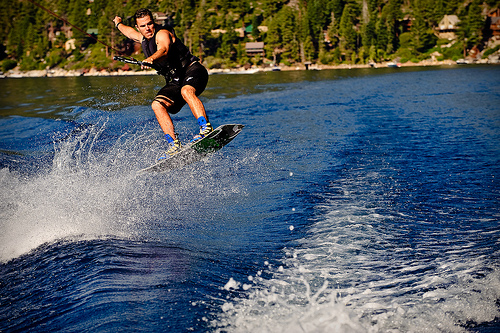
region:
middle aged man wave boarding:
[109, 12, 244, 175]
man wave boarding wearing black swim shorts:
[110, 11, 229, 163]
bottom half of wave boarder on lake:
[94, 94, 271, 253]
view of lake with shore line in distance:
[243, 3, 464, 154]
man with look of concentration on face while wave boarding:
[91, 7, 240, 168]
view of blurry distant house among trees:
[407, 7, 486, 49]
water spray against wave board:
[57, 126, 250, 253]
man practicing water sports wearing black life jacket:
[107, 11, 244, 172]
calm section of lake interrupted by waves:
[3, 86, 118, 145]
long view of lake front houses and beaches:
[214, 26, 380, 80]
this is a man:
[114, 3, 226, 128]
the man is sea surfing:
[98, 9, 225, 148]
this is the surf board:
[195, 118, 247, 167]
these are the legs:
[153, 87, 205, 127]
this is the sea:
[390, 93, 471, 166]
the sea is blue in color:
[393, 78, 485, 158]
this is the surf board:
[215, 120, 247, 146]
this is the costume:
[176, 42, 196, 74]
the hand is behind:
[112, 8, 131, 41]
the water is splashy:
[59, 123, 142, 185]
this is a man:
[110, 12, 222, 137]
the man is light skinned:
[153, 29, 170, 52]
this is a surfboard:
[165, 132, 232, 167]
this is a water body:
[303, 103, 466, 203]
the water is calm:
[309, 105, 454, 231]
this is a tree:
[336, 15, 361, 69]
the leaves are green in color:
[300, 34, 313, 57]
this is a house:
[243, 37, 268, 56]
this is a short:
[186, 67, 211, 88]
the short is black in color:
[190, 65, 205, 84]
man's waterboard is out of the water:
[72, 111, 288, 188]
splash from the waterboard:
[35, 120, 296, 263]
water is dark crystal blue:
[38, 227, 225, 320]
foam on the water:
[317, 161, 437, 330]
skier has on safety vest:
[132, 30, 221, 109]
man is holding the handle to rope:
[98, 49, 168, 88]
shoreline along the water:
[216, 59, 481, 74]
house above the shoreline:
[233, 31, 280, 60]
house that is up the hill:
[427, 12, 471, 50]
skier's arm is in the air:
[105, 8, 153, 50]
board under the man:
[101, 100, 251, 200]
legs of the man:
[140, 76, 215, 143]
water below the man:
[157, 187, 247, 272]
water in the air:
[45, 116, 116, 176]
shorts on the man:
[150, 55, 225, 105]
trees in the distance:
[260, 15, 385, 60]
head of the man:
[120, 5, 165, 41]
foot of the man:
[180, 111, 220, 146]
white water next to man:
[291, 252, 396, 318]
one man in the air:
[55, 8, 245, 175]